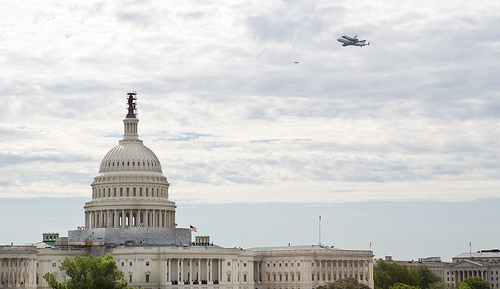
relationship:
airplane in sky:
[336, 34, 370, 48] [0, 0, 498, 249]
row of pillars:
[79, 195, 181, 229] [307, 261, 365, 286]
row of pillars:
[79, 195, 181, 229] [80, 204, 176, 228]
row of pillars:
[79, 195, 181, 229] [165, 256, 220, 284]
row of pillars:
[79, 195, 181, 229] [262, 263, 306, 285]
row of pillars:
[79, 195, 181, 229] [123, 122, 139, 135]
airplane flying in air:
[336, 34, 370, 48] [11, 13, 471, 183]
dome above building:
[80, 85, 181, 230] [13, 88, 376, 285]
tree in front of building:
[41, 249, 126, 287] [13, 88, 376, 285]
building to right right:
[442, 252, 499, 287] [385, 8, 485, 282]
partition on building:
[69, 226, 199, 247] [13, 88, 376, 285]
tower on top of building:
[120, 117, 143, 137] [13, 88, 376, 285]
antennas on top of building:
[126, 89, 136, 115] [13, 88, 376, 285]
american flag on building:
[182, 222, 198, 231] [13, 88, 376, 285]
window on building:
[141, 271, 151, 283] [13, 88, 376, 285]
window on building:
[241, 272, 249, 283] [13, 88, 376, 285]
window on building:
[444, 268, 450, 274] [444, 259, 497, 286]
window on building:
[293, 271, 299, 281] [444, 259, 497, 286]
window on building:
[136, 159, 143, 166] [379, 255, 446, 276]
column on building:
[196, 260, 206, 286] [28, 77, 400, 287]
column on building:
[132, 208, 143, 226] [13, 88, 376, 285]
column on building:
[121, 184, 145, 194] [13, 88, 376, 285]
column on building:
[166, 257, 172, 284] [13, 88, 376, 285]